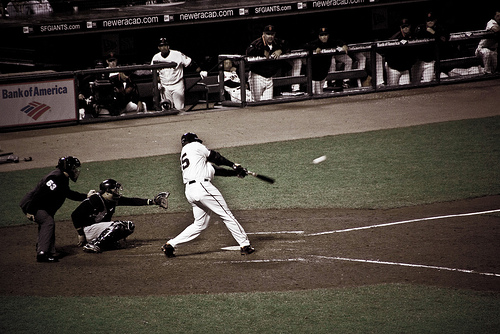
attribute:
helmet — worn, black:
[59, 156, 84, 184]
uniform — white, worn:
[167, 141, 250, 248]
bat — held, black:
[244, 169, 278, 190]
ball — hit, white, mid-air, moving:
[311, 156, 326, 163]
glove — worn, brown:
[234, 163, 248, 176]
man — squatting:
[71, 179, 176, 253]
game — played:
[3, 3, 499, 333]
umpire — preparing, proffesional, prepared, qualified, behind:
[19, 147, 88, 280]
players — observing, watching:
[77, 16, 356, 101]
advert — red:
[4, 83, 69, 120]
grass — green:
[292, 119, 488, 194]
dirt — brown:
[129, 259, 240, 279]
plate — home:
[215, 230, 265, 277]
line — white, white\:
[309, 209, 467, 242]